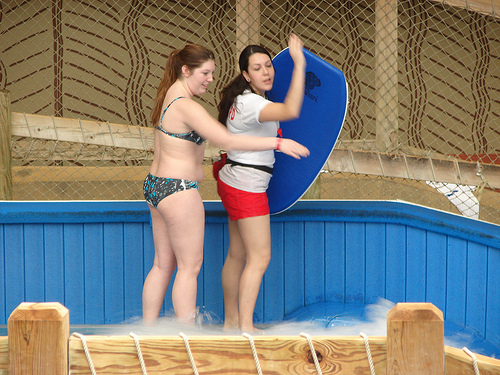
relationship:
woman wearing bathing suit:
[156, 36, 254, 354] [139, 95, 203, 208]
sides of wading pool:
[1, 198, 499, 358] [0, 197, 499, 373]